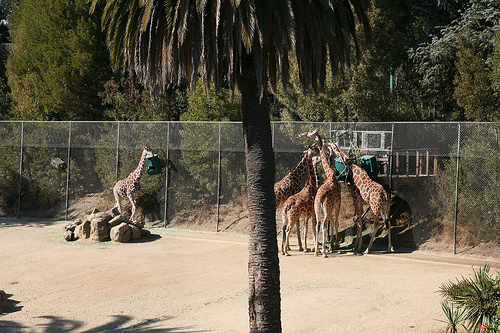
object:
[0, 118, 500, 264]
fence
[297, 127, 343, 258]
giraffes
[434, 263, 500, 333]
plant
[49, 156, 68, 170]
video camera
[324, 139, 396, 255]
giraffes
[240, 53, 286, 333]
tree trunk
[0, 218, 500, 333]
dirt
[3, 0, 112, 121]
tree top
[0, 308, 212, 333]
shadow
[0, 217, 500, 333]
ground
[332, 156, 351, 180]
container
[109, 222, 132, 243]
rocks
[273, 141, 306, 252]
giraffe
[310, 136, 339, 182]
necks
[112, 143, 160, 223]
animals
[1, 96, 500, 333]
area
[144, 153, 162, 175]
basket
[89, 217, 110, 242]
rocks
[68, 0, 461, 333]
tree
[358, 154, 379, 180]
bucket